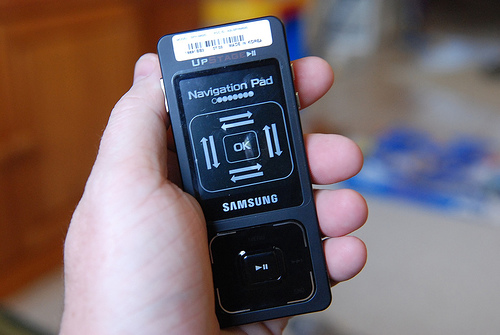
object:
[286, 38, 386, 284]
finger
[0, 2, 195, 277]
wall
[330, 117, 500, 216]
mat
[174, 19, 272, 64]
sticker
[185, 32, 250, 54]
barcode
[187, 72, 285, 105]
navigation pad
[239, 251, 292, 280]
button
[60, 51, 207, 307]
cabinet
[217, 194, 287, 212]
samsung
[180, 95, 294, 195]
track pad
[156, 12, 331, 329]
cell phone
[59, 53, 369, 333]
hand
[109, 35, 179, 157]
thumb